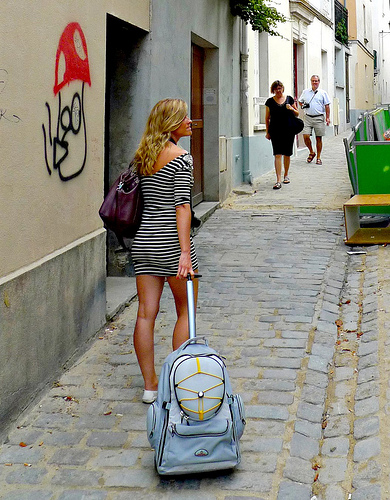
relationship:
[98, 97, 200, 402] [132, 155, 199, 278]
woman in dress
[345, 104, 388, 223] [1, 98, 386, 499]
bin in alley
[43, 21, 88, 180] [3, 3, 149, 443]
graffiti on wall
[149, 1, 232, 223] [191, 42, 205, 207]
building has entrance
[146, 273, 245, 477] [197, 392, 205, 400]
bag has latch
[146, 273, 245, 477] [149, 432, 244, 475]
luggage has wheels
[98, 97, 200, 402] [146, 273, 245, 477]
woman carries luggage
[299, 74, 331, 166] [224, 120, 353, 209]
pedestrian on sidewalk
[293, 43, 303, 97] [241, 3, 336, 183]
doorway to building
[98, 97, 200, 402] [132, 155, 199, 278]
woman wearing dress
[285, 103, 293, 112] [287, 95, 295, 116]
hand clutches strap